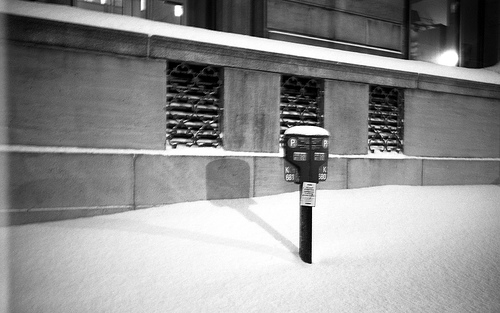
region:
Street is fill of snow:
[1, 176, 494, 309]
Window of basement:
[151, 55, 232, 170]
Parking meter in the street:
[266, 107, 336, 268]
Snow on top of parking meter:
[276, 117, 328, 137]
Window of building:
[241, 0, 421, 70]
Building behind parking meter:
[6, 0, 496, 215]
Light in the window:
[430, 45, 460, 70]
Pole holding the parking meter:
[291, 180, 326, 265]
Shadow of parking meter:
[196, 153, 286, 262]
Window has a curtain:
[238, 0, 413, 62]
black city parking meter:
[277, 97, 338, 278]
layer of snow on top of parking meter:
[279, 122, 334, 145]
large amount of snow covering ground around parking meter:
[146, 190, 489, 302]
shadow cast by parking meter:
[197, 140, 301, 268]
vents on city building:
[145, 47, 470, 152]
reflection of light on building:
[397, 21, 476, 74]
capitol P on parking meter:
[278, 132, 303, 159]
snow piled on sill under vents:
[140, 125, 247, 162]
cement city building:
[21, 19, 465, 171]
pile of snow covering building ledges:
[60, 26, 497, 72]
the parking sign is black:
[272, 121, 339, 273]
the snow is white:
[87, 236, 256, 291]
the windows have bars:
[171, 66, 213, 143]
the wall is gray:
[52, 66, 146, 162]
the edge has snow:
[122, 17, 374, 83]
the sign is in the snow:
[265, 112, 338, 288]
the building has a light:
[413, 42, 493, 83]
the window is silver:
[167, 63, 213, 146]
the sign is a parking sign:
[286, 126, 334, 263]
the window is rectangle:
[161, 43, 238, 158]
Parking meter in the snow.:
[265, 87, 365, 309]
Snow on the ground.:
[115, 225, 195, 304]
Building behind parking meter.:
[145, 25, 452, 293]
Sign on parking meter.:
[285, 167, 335, 226]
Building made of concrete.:
[55, 24, 498, 219]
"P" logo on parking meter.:
[282, 128, 312, 184]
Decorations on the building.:
[117, 47, 287, 199]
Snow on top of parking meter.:
[279, 122, 341, 151]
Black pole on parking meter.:
[300, 196, 325, 276]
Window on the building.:
[407, 5, 478, 135]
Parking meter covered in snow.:
[282, 122, 329, 264]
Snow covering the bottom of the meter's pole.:
[272, 215, 334, 304]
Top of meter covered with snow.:
[279, 118, 334, 140]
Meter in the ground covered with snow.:
[150, 124, 432, 299]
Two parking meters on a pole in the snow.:
[275, 122, 335, 264]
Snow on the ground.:
[47, 226, 277, 307]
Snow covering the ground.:
[346, 203, 484, 303]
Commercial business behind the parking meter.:
[0, 2, 497, 227]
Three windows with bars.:
[147, 56, 416, 156]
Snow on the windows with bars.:
[156, 59, 407, 159]